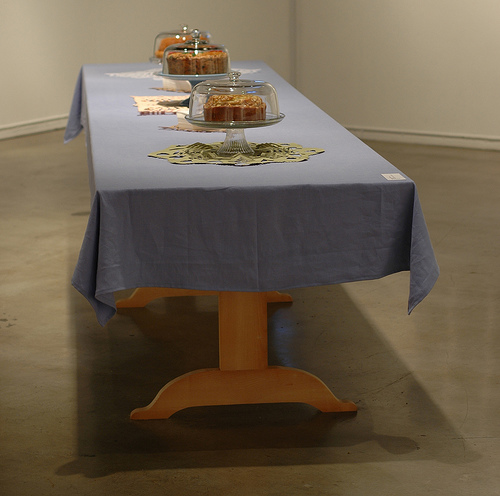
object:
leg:
[130, 292, 360, 421]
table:
[82, 61, 414, 420]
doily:
[148, 141, 322, 166]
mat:
[161, 120, 239, 134]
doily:
[106, 67, 259, 80]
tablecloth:
[63, 58, 439, 327]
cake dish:
[185, 70, 286, 156]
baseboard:
[344, 122, 499, 152]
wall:
[0, 0, 499, 150]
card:
[383, 172, 405, 181]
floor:
[0, 124, 499, 496]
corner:
[69, 189, 137, 327]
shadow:
[55, 228, 477, 478]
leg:
[116, 287, 294, 308]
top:
[83, 59, 410, 191]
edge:
[92, 178, 414, 201]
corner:
[407, 185, 439, 317]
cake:
[204, 94, 267, 122]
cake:
[168, 50, 228, 76]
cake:
[157, 34, 206, 58]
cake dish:
[153, 29, 241, 107]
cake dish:
[150, 25, 214, 62]